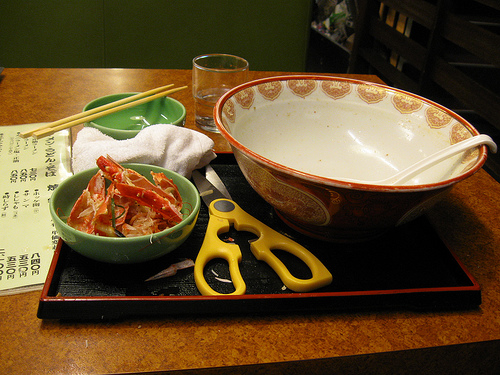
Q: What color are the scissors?
A: Yellow.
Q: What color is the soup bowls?
A: Green.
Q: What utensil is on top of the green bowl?
A: Chopsticks.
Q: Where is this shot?
A: Table.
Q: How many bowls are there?
A: 3.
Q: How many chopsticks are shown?
A: 2.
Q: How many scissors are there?
A: 1.